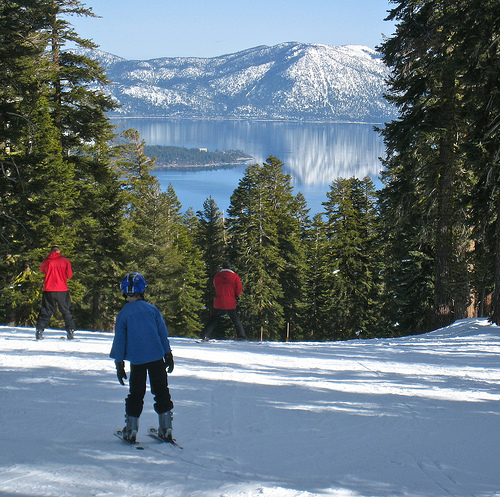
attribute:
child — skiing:
[108, 267, 177, 439]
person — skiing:
[34, 242, 78, 341]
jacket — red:
[38, 252, 72, 294]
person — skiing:
[199, 260, 245, 340]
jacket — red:
[209, 270, 243, 311]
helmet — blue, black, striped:
[118, 268, 146, 295]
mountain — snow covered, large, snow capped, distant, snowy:
[34, 40, 430, 124]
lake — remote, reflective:
[58, 116, 407, 226]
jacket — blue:
[109, 300, 172, 365]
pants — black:
[36, 288, 74, 334]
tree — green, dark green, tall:
[222, 163, 289, 341]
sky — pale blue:
[57, 0, 411, 62]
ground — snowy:
[1, 316, 499, 495]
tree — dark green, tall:
[123, 181, 182, 338]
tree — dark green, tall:
[325, 177, 380, 338]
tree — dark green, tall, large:
[1, 0, 84, 328]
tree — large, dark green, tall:
[44, 1, 128, 337]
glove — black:
[115, 360, 128, 389]